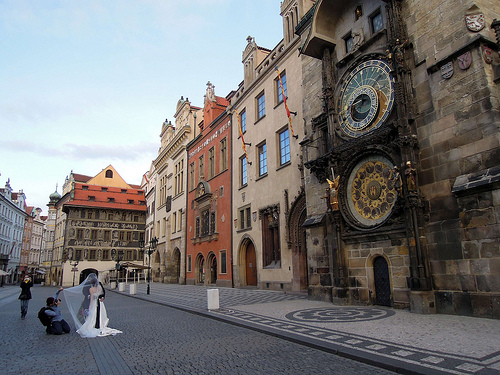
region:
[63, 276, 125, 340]
bride in a white dress with a long flowy veil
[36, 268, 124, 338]
photographer crouching down to get a picture of the bride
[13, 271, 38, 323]
person walking down the street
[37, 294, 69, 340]
guy crouching down wearing a black backpack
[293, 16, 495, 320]
old stone building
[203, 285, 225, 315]
white rectangle on the side of the street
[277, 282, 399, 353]
circular stone design decorating the sidewalk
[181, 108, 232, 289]
reddish orange building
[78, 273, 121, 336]
black fabric wrapped around the woman's shoulder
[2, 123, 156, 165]
thin cloud in the sky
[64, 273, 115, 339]
Bride and groom being photgraphed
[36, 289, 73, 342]
Photographer down on knees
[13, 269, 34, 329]
Bystander taking picture of couple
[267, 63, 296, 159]
Flag hanging on building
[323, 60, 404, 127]
Decorative style clock on building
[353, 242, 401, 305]
Arch way type entry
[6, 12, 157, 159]
Evening sky appears cloudless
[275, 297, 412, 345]
Decorative pattern on sidewalk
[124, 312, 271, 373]
Street is clean, and sweeped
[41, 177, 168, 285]
Older style building in background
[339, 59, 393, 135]
a large and unusual clock attached to the building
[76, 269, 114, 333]
a married couple taking wedding photos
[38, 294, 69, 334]
the photographer taking photos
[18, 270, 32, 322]
a person standing in the street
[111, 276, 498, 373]
a sidewalk in front of the buildings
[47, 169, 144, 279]
a building at the end of the road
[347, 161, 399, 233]
a window made of stainded glass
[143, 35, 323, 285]
a line of buildings next to one another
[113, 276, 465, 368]
the sidewalk in front of the buildings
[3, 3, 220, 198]
the bright blue sky above everything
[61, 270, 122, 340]
A bride and groom.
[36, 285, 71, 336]
A man on his knees.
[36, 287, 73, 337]
A man taking pictures.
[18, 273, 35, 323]
A lady taking pictures.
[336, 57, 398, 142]
A clock on a tower.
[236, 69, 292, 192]
Windows on a building.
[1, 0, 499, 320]
Buildings in the city.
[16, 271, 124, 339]
Four people in the street.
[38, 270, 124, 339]
Three people in the street.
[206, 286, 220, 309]
A white trash can.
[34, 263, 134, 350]
a couple with a photographer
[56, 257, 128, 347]
the bride and groom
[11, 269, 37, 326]
a person in black coat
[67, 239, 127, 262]
a row of windows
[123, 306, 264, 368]
a cobble stone street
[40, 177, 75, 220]
a decorative roof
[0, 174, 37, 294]
a tall white building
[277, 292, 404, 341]
a decorative piece of sidewalk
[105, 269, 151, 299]
a row of white posts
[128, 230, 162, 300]
a decorative street lamp